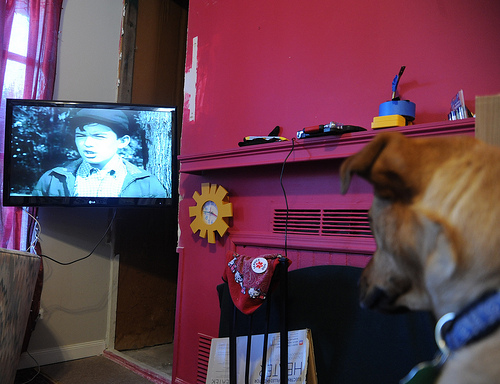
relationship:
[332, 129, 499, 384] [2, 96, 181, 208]
dog watching television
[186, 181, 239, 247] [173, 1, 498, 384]
clock on wall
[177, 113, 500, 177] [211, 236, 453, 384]
mantle above fireplace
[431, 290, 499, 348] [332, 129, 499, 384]
collar of dog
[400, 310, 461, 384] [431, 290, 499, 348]
ring on collar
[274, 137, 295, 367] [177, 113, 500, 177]
cord hanging from mantle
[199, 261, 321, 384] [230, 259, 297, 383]
bag with straps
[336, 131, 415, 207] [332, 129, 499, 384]
ear of dog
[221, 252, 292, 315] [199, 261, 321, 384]
bandana on bag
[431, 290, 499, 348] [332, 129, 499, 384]
collar on dog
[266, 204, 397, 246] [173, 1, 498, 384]
grates on wall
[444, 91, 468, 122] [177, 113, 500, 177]
items on mantle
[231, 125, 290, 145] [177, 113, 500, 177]
items on mantle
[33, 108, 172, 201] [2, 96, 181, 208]
man on television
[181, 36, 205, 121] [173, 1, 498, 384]
patch on wall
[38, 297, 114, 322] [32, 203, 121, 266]
shadow from cord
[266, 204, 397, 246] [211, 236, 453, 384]
grates above fireplace